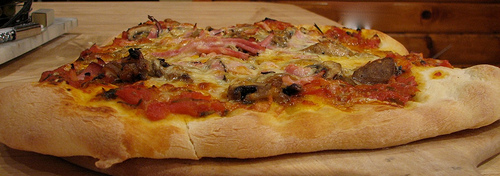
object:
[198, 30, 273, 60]
ham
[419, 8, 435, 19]
knot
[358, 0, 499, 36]
wood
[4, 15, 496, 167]
pizza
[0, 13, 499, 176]
block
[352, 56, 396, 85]
meat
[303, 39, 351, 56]
meat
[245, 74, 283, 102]
meat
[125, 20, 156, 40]
meat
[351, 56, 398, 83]
sausage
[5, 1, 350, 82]
table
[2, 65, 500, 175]
pizza peel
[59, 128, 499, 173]
peel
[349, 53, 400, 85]
mushroom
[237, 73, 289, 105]
mushroom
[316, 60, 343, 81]
mushroom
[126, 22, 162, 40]
mushroom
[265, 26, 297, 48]
mushroom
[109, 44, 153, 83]
meat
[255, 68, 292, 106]
sausage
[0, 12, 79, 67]
board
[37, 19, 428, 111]
cheese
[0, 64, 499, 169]
crust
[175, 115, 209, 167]
crack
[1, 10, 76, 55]
item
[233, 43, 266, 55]
ham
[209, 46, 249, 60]
ham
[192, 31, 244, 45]
ham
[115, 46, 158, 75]
sausage